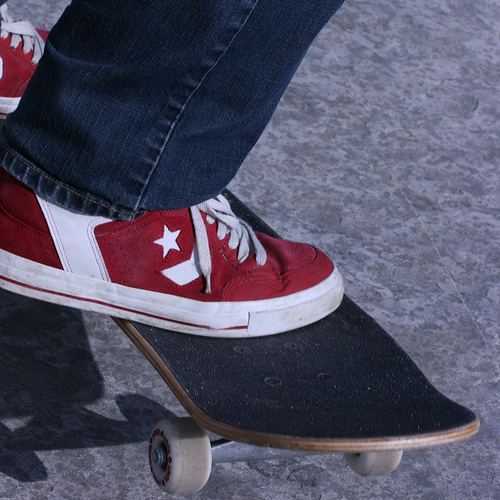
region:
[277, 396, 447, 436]
black skateboard top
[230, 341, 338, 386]
bolts securing skateboard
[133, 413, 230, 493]
white plastic skateboard wheel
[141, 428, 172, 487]
red writing on side of white wheel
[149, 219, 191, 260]
star design on side of tennis shoe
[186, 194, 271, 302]
white shoe laces on tennis shoe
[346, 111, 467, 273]
tile on floor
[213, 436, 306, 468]
silver metal skateboard axel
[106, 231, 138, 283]
small air holes on side of shoe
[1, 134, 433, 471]
person standing on skateboard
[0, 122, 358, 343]
A red rubber shoe in the picture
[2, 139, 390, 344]
A red and white rubber shoe in the picture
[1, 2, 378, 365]
Red and white rubber shoes in the picture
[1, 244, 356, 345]
Sole of a rubber shoe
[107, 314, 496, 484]
The skate board is black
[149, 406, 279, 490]
Wheel of a skate board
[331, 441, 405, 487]
Wheel of a skate board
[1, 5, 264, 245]
Blue jeans in the picture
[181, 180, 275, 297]
Shoe race in the picture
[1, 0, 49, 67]
Shoe race in the picture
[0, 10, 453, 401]
person skateboarding on board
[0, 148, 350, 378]
red converse on feet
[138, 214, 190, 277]
white star on red shoes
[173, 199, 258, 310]
white shoe laces on red shoes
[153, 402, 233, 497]
white wheels on board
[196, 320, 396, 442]
black grip tape on board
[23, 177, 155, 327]
white and red design on board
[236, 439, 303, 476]
silver trucks on board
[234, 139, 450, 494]
concrete ground beneath board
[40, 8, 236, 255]
jean pants on legs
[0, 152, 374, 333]
red sneaker with white star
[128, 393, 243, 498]
white skate board wheel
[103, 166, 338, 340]
red sneaker with white laces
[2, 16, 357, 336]
bluejeans and red shoe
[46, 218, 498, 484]
toe of shoe on skate board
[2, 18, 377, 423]
feet on a skateboard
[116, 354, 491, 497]
two front wheels of a skateboard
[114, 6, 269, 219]
seam of pants leg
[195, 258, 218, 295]
aglet on white shoelace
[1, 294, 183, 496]
shadow of a skateboard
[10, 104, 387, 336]
Red and white Converse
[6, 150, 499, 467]
Skate shoes and boarding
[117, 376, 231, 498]
Polyurethane wheels for smooth performance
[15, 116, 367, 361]
Blue jeans and red sneakers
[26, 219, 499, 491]
Skating on a smooth granite surface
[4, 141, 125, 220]
Orange stitching on seam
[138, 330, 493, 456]
Rough no slip surface on board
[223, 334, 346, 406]
Four bolts securing the wheels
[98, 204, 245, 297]
Classic Converse logo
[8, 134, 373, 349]
Red suede converse sneakers